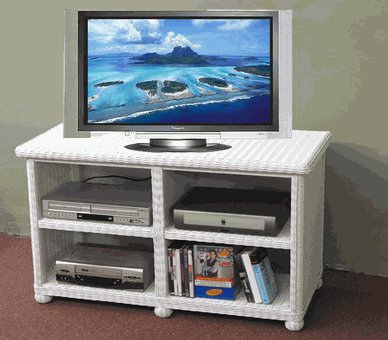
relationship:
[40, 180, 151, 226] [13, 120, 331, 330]
dvd/vcr combo on stand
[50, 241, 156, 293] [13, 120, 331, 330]
vcr on stand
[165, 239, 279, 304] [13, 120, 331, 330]
collection on stand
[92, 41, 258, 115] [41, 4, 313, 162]
islands on screen